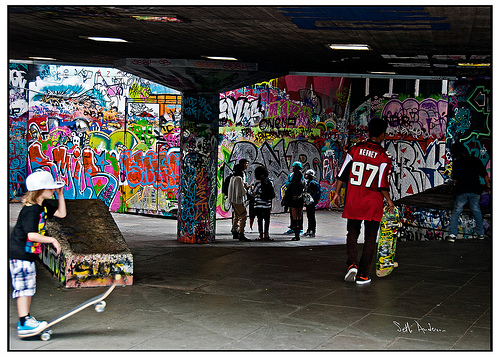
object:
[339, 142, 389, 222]
shirt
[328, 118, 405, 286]
man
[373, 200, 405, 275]
board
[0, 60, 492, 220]
wall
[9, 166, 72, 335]
boy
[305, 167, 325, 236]
people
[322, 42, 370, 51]
light